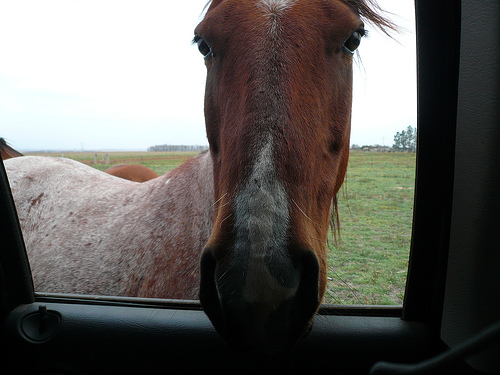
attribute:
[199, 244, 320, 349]
nose — black, inside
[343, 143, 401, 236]
ground — here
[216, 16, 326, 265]
head — white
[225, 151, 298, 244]
spot — grey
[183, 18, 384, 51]
eyes — brown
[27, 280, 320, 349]
door — locked, inside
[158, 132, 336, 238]
hair — grey, around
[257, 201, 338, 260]
whiskers — grey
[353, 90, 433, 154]
trees — green, small, distant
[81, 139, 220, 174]
field — green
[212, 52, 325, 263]
face — brown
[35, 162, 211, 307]
body — white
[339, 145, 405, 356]
grass — green, brown, patchy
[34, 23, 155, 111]
sky — white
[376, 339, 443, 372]
knob — interior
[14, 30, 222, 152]
clouds — white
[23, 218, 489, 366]
interior — black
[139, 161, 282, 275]
patch — white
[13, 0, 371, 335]
horse — white, looking, brown, sticking, here